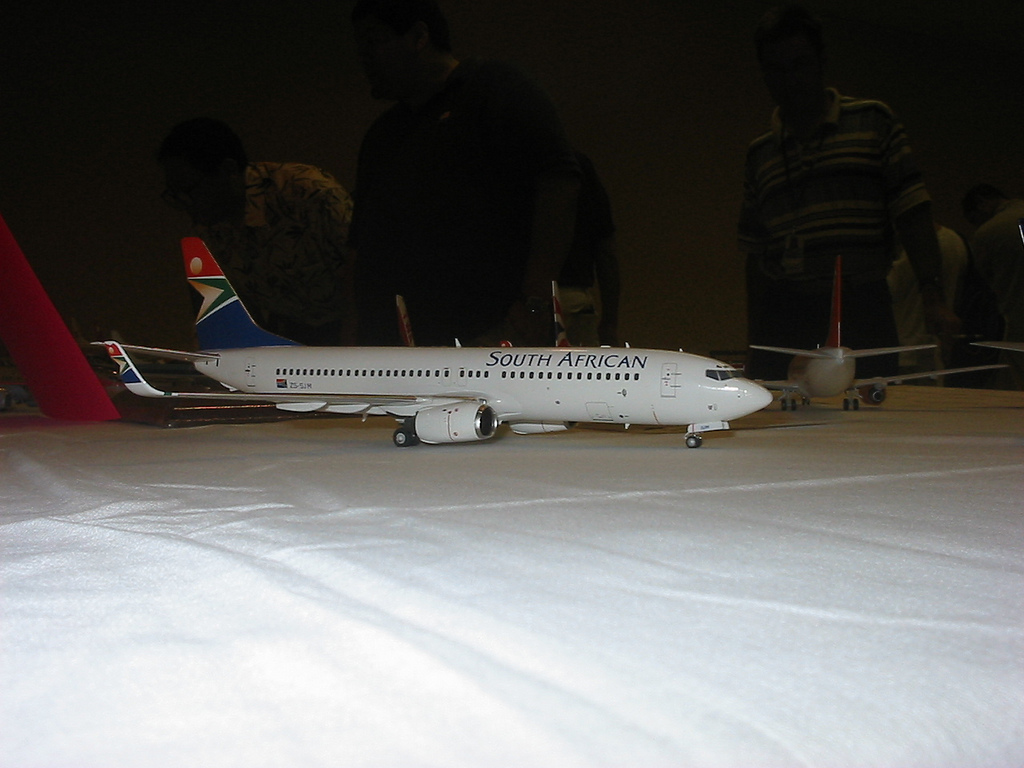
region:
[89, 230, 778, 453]
south african airlines plane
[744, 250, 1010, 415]
model plane with red tail wing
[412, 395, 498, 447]
engine on a plane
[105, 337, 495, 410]
the right wing of a plane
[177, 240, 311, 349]
the tail wing of a plane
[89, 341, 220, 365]
the tail rudder of a plane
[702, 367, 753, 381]
the windshield of a plane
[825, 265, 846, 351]
a red tail of a wing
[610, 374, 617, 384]
a window on a building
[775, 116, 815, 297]
Black lanyard around the man's neck.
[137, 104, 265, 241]
Man with glasses on his face.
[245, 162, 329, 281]
Flowers on the man's shirt.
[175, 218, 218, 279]
Red and white paint on the tip of the plane.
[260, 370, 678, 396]
Line of plane windows on the side.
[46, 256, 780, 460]
red white and blue plane on ground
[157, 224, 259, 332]
red white and blue tail of plane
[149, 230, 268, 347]
tail of white plane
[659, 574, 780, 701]
gray pavement on air strip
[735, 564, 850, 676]
gray pavement on air strip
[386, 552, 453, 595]
gray pavement on air strip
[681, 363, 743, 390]
window on the plane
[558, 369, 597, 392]
window on the plane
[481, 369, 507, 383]
window on the plane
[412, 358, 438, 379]
window on the plane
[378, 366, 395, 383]
window on the plane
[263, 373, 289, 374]
window on the plane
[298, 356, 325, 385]
window on the plane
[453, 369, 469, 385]
window on the plane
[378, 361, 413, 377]
window on the plane